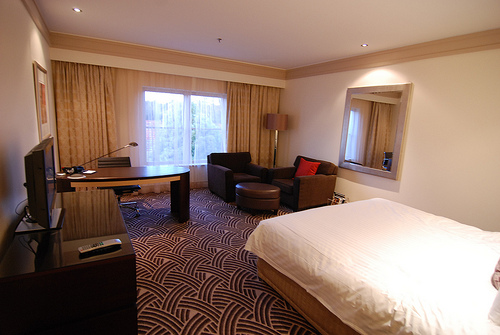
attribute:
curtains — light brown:
[53, 57, 281, 194]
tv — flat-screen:
[16, 133, 62, 230]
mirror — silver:
[334, 82, 414, 183]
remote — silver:
[74, 233, 120, 256]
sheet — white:
[245, 197, 497, 331]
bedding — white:
[242, 196, 497, 330]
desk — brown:
[56, 159, 191, 227]